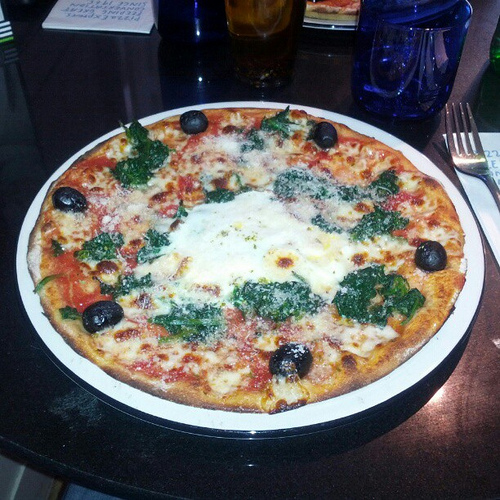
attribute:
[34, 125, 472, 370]
pizza — round, saucy, yellow, crusted, big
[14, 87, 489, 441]
plate — white, flat, round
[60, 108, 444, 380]
olives — black, large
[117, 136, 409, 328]
vegetables — green, dark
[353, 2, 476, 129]
cup — glass, blue, shiny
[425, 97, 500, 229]
fork — shiny, long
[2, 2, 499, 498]
table — curved, wooden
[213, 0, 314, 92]
glass — brown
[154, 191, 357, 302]
cheese — melted, sprinkled